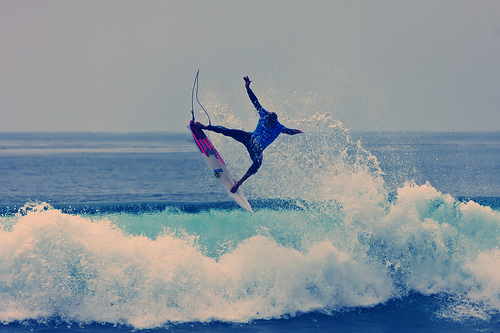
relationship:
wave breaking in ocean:
[3, 206, 498, 321] [1, 131, 498, 331]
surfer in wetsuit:
[184, 69, 309, 204] [193, 85, 293, 195]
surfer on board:
[191, 75, 311, 195] [187, 118, 254, 211]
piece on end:
[182, 97, 199, 127] [187, 71, 212, 136]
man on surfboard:
[169, 57, 323, 229] [180, 116, 251, 222]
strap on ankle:
[203, 120, 213, 131] [199, 121, 209, 135]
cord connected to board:
[187, 67, 216, 127] [187, 118, 254, 211]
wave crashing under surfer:
[3, 206, 498, 321] [191, 78, 301, 216]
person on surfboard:
[196, 72, 308, 194] [188, 119, 253, 214]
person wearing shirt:
[196, 78, 308, 195] [250, 105, 294, 155]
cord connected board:
[187, 67, 216, 127] [181, 117, 268, 215]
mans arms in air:
[240, 77, 320, 139] [111, 73, 216, 291]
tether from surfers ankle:
[190, 69, 212, 125] [221, 185, 237, 231]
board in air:
[187, 118, 254, 211] [111, 108, 149, 184]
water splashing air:
[7, 127, 484, 292] [32, 54, 144, 144]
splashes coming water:
[305, 144, 387, 199] [4, 168, 482, 295]